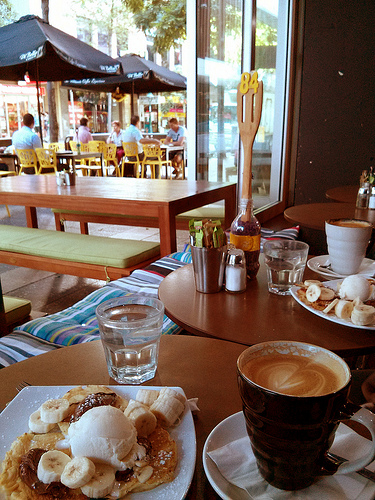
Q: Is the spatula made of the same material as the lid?
A: No, the spatula is made of wood and the lid is made of metal.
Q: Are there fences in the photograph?
A: No, there are no fences.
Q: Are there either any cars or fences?
A: No, there are no fences or cars.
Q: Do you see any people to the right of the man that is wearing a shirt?
A: Yes, there are people to the right of the man.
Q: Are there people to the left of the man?
A: No, the people are to the right of the man.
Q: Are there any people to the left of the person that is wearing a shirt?
A: No, the people are to the right of the man.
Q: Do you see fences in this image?
A: No, there are no fences.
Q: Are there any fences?
A: No, there are no fences.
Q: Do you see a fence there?
A: No, there are no fences.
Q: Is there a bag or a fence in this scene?
A: No, there are no fences or bags.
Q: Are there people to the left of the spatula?
A: Yes, there is a person to the left of the spatula.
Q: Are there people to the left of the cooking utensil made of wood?
A: Yes, there is a person to the left of the spatula.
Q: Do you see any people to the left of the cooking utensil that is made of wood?
A: Yes, there is a person to the left of the spatula.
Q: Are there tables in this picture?
A: Yes, there is a table.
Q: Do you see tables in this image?
A: Yes, there is a table.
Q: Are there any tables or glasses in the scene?
A: Yes, there is a table.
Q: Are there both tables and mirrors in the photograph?
A: No, there is a table but no mirrors.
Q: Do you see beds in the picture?
A: No, there are no beds.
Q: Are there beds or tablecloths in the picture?
A: No, there are no beds or tablecloths.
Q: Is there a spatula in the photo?
A: Yes, there is a spatula.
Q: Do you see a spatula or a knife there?
A: Yes, there is a spatula.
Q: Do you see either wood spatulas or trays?
A: Yes, there is a wood spatula.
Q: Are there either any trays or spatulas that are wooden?
A: Yes, the spatula is wooden.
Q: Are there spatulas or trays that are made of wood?
A: Yes, the spatula is made of wood.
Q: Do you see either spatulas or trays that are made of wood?
A: Yes, the spatula is made of wood.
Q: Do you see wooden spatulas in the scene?
A: Yes, there is a wood spatula.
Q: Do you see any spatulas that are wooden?
A: Yes, there is a spatula that is wooden.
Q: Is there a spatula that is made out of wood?
A: Yes, there is a spatula that is made of wood.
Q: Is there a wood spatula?
A: Yes, there is a spatula that is made of wood.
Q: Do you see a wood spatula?
A: Yes, there is a spatula that is made of wood.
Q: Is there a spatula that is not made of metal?
A: Yes, there is a spatula that is made of wood.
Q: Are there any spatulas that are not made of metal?
A: Yes, there is a spatula that is made of wood.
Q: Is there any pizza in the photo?
A: No, there are no pizzas.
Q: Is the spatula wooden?
A: Yes, the spatula is wooden.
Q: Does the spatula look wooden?
A: Yes, the spatula is wooden.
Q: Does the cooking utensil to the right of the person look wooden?
A: Yes, the spatula is wooden.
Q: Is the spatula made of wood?
A: Yes, the spatula is made of wood.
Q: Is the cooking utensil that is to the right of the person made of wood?
A: Yes, the spatula is made of wood.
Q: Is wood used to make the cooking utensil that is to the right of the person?
A: Yes, the spatula is made of wood.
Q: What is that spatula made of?
A: The spatula is made of wood.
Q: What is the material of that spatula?
A: The spatula is made of wood.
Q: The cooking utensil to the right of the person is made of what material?
A: The spatula is made of wood.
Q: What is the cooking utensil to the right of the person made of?
A: The spatula is made of wood.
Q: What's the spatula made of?
A: The spatula is made of wood.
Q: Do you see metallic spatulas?
A: No, there is a spatula but it is wooden.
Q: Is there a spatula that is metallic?
A: No, there is a spatula but it is wooden.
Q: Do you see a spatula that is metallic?
A: No, there is a spatula but it is wooden.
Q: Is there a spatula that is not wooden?
A: No, there is a spatula but it is wooden.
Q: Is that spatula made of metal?
A: No, the spatula is made of wood.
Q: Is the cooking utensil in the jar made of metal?
A: No, the spatula is made of wood.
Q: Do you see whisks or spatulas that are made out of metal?
A: No, there is a spatula but it is made of wood.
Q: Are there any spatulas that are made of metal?
A: No, there is a spatula but it is made of wood.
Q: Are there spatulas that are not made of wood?
A: No, there is a spatula but it is made of wood.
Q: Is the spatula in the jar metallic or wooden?
A: The spatula is wooden.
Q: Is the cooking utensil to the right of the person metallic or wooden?
A: The spatula is wooden.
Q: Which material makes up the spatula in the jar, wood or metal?
A: The spatula is made of wood.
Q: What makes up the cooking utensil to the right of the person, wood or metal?
A: The spatula is made of wood.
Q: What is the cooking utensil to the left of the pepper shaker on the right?
A: The cooking utensil is a spatula.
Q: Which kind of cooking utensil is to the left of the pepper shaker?
A: The cooking utensil is a spatula.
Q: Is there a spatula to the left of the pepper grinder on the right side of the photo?
A: Yes, there is a spatula to the left of the pepper grinder.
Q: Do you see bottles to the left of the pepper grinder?
A: No, there is a spatula to the left of the pepper grinder.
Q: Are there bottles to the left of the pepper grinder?
A: No, there is a spatula to the left of the pepper grinder.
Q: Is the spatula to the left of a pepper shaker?
A: Yes, the spatula is to the left of a pepper shaker.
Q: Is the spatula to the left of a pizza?
A: No, the spatula is to the left of a pepper shaker.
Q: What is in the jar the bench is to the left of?
A: The spatula is in the jar.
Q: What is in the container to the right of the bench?
A: The spatula is in the jar.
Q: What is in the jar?
A: The spatula is in the jar.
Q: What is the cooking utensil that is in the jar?
A: The cooking utensil is a spatula.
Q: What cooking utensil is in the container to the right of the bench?
A: The cooking utensil is a spatula.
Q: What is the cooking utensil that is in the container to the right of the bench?
A: The cooking utensil is a spatula.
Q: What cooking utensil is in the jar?
A: The cooking utensil is a spatula.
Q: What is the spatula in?
A: The spatula is in the jar.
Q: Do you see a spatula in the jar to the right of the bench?
A: Yes, there is a spatula in the jar.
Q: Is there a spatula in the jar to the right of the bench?
A: Yes, there is a spatula in the jar.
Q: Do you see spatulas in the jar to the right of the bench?
A: Yes, there is a spatula in the jar.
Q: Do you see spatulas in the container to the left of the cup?
A: Yes, there is a spatula in the jar.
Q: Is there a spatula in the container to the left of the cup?
A: Yes, there is a spatula in the jar.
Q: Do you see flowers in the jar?
A: No, there is a spatula in the jar.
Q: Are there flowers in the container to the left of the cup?
A: No, there is a spatula in the jar.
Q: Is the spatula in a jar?
A: Yes, the spatula is in a jar.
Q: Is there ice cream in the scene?
A: Yes, there is ice cream.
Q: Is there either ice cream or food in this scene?
A: Yes, there is ice cream.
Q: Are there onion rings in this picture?
A: No, there are no onion rings.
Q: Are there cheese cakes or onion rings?
A: No, there are no onion rings or cheese cakes.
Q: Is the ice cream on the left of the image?
A: Yes, the ice cream is on the left of the image.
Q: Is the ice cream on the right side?
A: No, the ice cream is on the left of the image.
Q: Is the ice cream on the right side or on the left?
A: The ice cream is on the left of the image.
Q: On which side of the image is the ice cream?
A: The ice cream is on the left of the image.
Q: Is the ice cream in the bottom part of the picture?
A: Yes, the ice cream is in the bottom of the image.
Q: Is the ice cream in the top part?
A: No, the ice cream is in the bottom of the image.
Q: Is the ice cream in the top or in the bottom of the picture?
A: The ice cream is in the bottom of the image.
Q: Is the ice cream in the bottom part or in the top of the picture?
A: The ice cream is in the bottom of the image.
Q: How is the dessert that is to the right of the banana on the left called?
A: The dessert is ice cream.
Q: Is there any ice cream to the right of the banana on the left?
A: Yes, there is ice cream to the right of the banana.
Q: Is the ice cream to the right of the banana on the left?
A: Yes, the ice cream is to the right of the banana.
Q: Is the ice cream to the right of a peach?
A: No, the ice cream is to the right of the banana.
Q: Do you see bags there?
A: No, there are no bags.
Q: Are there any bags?
A: No, there are no bags.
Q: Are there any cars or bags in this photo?
A: No, there are no bags or cars.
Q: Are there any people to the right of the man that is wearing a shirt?
A: Yes, there is a person to the right of the man.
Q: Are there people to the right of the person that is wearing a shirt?
A: Yes, there is a person to the right of the man.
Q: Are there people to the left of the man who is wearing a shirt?
A: No, the person is to the right of the man.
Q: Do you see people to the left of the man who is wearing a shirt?
A: No, the person is to the right of the man.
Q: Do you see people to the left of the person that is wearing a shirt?
A: No, the person is to the right of the man.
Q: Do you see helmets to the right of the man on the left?
A: No, there is a person to the right of the man.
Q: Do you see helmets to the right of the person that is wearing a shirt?
A: No, there is a person to the right of the man.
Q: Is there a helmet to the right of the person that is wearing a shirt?
A: No, there is a person to the right of the man.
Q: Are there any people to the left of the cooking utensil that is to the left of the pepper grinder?
A: Yes, there is a person to the left of the spatula.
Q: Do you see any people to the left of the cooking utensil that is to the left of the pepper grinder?
A: Yes, there is a person to the left of the spatula.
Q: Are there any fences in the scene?
A: No, there are no fences.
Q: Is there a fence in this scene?
A: No, there are no fences.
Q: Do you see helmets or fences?
A: No, there are no fences or helmets.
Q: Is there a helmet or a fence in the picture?
A: No, there are no fences or helmets.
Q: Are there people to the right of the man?
A: Yes, there is a person to the right of the man.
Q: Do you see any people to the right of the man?
A: Yes, there is a person to the right of the man.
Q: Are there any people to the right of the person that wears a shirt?
A: Yes, there is a person to the right of the man.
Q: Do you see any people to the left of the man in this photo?
A: No, the person is to the right of the man.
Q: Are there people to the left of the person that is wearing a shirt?
A: No, the person is to the right of the man.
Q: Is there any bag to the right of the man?
A: No, there is a person to the right of the man.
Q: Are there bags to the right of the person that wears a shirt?
A: No, there is a person to the right of the man.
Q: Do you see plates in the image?
A: Yes, there is a plate.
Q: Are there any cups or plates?
A: Yes, there is a plate.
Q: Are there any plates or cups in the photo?
A: Yes, there is a plate.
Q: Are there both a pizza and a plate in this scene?
A: No, there is a plate but no pizzas.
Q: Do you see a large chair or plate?
A: Yes, there is a large plate.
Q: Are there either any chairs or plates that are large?
A: Yes, the plate is large.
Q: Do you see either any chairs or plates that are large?
A: Yes, the plate is large.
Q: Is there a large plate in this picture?
A: Yes, there is a large plate.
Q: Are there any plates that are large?
A: Yes, there is a plate that is large.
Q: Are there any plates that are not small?
A: Yes, there is a large plate.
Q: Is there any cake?
A: No, there are no cakes.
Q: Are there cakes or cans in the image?
A: No, there are no cakes or cans.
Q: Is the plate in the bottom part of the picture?
A: Yes, the plate is in the bottom of the image.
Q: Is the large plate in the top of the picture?
A: No, the plate is in the bottom of the image.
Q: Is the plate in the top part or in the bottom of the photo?
A: The plate is in the bottom of the image.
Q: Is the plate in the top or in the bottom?
A: The plate is in the bottom of the image.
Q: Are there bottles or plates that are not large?
A: No, there is a plate but it is large.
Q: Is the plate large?
A: Yes, the plate is large.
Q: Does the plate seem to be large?
A: Yes, the plate is large.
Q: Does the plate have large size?
A: Yes, the plate is large.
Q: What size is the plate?
A: The plate is large.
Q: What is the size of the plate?
A: The plate is large.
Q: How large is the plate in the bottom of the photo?
A: The plate is large.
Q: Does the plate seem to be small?
A: No, the plate is large.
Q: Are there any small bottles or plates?
A: No, there is a plate but it is large.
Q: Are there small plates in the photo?
A: No, there is a plate but it is large.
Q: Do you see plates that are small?
A: No, there is a plate but it is large.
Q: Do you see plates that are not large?
A: No, there is a plate but it is large.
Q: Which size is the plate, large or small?
A: The plate is large.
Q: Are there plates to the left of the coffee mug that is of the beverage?
A: Yes, there is a plate to the left of the coffee mug.